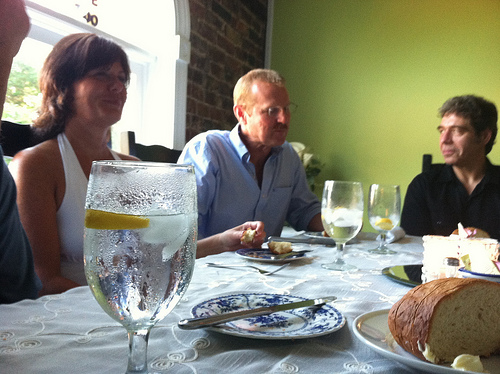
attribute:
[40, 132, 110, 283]
halter — white 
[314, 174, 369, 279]
glass — half full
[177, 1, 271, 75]
brick — red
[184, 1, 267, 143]
wall — in the picture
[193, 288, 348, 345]
dish — blue, white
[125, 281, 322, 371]
plate — round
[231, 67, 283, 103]
hair — brown 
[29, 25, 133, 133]
hair — brown 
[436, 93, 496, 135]
hair — brown 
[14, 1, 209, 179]
window — in the picture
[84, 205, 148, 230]
lemon — in the picture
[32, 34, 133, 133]
hair — dark, brown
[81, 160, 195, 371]
glass — full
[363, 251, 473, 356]
bread — in the picture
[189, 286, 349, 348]
plate — small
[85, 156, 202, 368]
glass — in the picture, clear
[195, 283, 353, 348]
plate — blue , white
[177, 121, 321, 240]
shirt — denim 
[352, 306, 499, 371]
plate — white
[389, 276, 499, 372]
bread — fresh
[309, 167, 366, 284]
glass — clear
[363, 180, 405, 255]
glass — in the picture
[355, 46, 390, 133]
wall — lime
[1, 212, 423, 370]
tablecloth — white